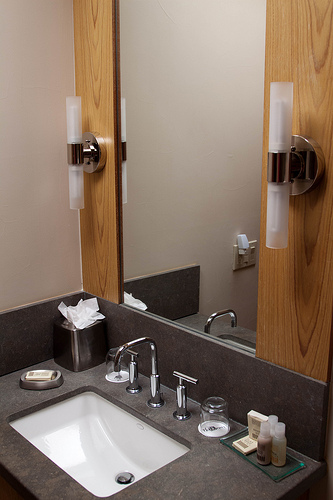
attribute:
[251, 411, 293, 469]
bottles — three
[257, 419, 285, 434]
caps — white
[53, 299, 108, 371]
tissue box — silver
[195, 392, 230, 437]
glass — water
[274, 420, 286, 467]
shampoo — liquid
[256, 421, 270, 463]
conditioner — liquid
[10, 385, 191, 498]
sink — white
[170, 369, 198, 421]
fixture — weird, modern looking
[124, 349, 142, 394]
fixture — weird, modern looking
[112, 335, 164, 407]
fixture — weird, modern looking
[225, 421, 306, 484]
tray — glass, green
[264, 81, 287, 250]
sconce — interesting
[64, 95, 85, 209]
sconce — interesting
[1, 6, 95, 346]
wall — white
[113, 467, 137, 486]
drain — silver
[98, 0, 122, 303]
frame — wooden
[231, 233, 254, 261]
light — night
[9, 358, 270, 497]
vanity — gray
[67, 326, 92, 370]
reflection — light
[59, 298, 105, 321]
tissues — white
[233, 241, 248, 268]
socket — wall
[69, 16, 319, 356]
frame — wood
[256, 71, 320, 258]
lamp — long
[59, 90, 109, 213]
lamp — long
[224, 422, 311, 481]
tray — green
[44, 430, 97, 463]
reflection — light